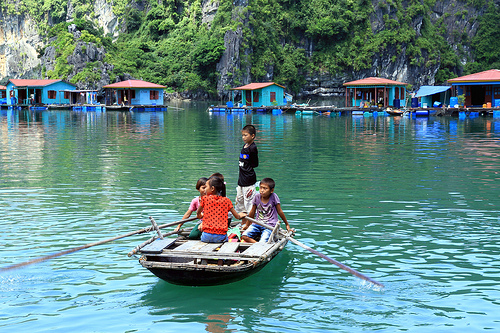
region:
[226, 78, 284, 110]
Hut on the river.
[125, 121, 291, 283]
Children riding on a boat.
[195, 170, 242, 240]
Girl moving the boat with oars.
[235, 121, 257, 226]
Boy standing on a boat.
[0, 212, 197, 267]
Girl using an oar.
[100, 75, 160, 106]
Hut in front of the mountain on the river.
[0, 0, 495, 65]
Mountain behind the huts on a river.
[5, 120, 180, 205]
A body of water.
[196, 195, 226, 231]
Girl wearing a red and black blouse.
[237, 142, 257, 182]
Boy in a black t-shirt.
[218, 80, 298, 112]
Blue boat house on a lake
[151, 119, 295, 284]
Four small children on a boat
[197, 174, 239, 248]
Very young girl in an orange shirt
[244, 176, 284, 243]
Young boy in a purple shirt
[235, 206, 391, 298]
Long boat oar for a small boat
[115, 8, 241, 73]
Beautiful green vegetation on a mountain side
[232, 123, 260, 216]
Young boy standing on a small boat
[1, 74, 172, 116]
Small blue boat houses on a lake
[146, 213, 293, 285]
A small boat on a lake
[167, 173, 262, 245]
Young girl with two oars in her hands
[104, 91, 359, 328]
children paddling a boat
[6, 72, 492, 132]
a community of houses on a river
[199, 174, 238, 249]
a little girl wearing a red top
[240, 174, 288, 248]
a boy looking at the sky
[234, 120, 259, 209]
a young boy standing in a boat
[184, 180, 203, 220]
a little girl wearing a pink shirt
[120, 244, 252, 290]
a wooden boat floating on a lake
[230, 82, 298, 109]
a blue house at the bottom of a moutain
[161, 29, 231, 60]
trees growing out of a mountain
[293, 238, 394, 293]
an oar in the water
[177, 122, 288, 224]
Four children in a small boat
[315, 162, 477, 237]
The calm green river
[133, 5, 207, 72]
Green bushes around the rocks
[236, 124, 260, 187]
A small boy in dark top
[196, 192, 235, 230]
A girl with red dotted top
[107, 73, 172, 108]
Blue boat house flouting on the waters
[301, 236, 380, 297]
One of the oars in action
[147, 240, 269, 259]
A few wood boards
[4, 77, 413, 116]
Four blue boat houses on the waters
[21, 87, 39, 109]
A person outside the boat house..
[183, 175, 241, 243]
Girl in orange top rowing her boat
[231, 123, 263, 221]
Young boy in black shirt riding atop the boat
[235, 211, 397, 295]
An oar used to steer the boat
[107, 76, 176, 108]
A blue hut on the water's edge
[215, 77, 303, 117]
A blue hut at the edge of the lake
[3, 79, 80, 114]
A blue residence floating atop the water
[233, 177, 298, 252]
A boy in purple sitting in the boat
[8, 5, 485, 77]
Moss and greenery adorning the cliffside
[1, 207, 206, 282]
A long oar, useful for steering a boat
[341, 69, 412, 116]
A blue abode set back from the waterside